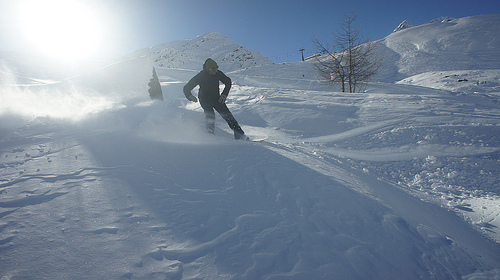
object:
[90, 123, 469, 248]
snow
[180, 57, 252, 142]
man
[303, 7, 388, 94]
trees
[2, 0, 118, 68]
sun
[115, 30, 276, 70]
mountain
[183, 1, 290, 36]
sky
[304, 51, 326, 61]
building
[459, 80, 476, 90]
rocks